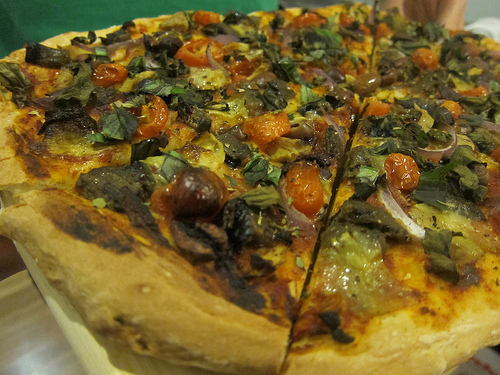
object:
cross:
[6, 6, 72, 28]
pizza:
[0, 9, 499, 366]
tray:
[11, 229, 282, 374]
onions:
[375, 186, 426, 238]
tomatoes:
[174, 38, 231, 67]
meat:
[25, 41, 72, 67]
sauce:
[189, 68, 233, 91]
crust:
[12, 161, 333, 374]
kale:
[140, 78, 213, 117]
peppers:
[278, 55, 312, 90]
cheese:
[374, 227, 459, 298]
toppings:
[272, 29, 344, 64]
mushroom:
[100, 28, 130, 43]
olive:
[352, 71, 382, 96]